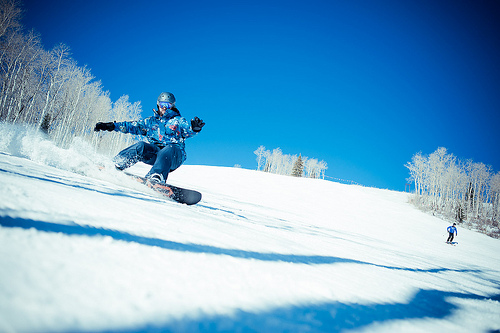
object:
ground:
[2, 201, 177, 302]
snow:
[243, 185, 371, 206]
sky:
[72, 0, 499, 105]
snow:
[145, 278, 274, 325]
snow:
[40, 132, 70, 160]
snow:
[284, 244, 393, 309]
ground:
[372, 251, 450, 318]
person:
[94, 91, 207, 184]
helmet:
[156, 91, 177, 108]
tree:
[251, 148, 284, 171]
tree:
[477, 165, 499, 224]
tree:
[428, 164, 442, 206]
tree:
[56, 66, 88, 144]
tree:
[0, 32, 27, 123]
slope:
[2, 165, 484, 331]